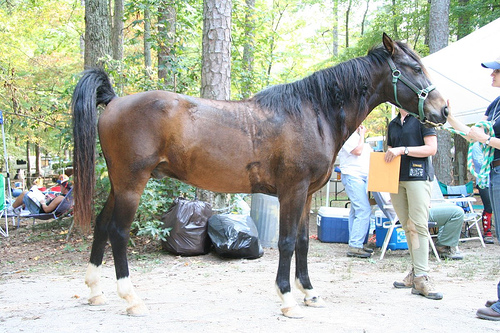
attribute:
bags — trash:
[163, 188, 270, 262]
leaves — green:
[175, 17, 194, 50]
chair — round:
[20, 184, 91, 248]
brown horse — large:
[72, 58, 402, 283]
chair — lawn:
[358, 124, 498, 251]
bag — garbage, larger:
[158, 194, 209, 254]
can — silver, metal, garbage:
[248, 160, 335, 271]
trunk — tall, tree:
[177, 16, 258, 103]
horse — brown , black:
[40, 67, 352, 276]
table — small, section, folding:
[327, 170, 352, 209]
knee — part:
[274, 235, 299, 259]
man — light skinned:
[369, 93, 440, 255]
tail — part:
[71, 153, 101, 234]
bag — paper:
[169, 199, 259, 256]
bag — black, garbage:
[207, 213, 264, 258]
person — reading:
[0, 165, 82, 231]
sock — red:
[467, 207, 484, 240]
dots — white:
[480, 212, 484, 231]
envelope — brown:
[369, 150, 401, 190]